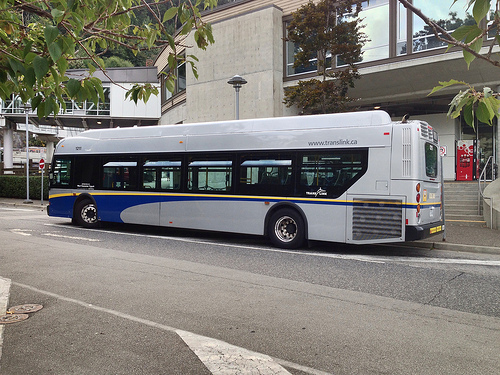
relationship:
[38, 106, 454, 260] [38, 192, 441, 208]
bus has a yellow stripe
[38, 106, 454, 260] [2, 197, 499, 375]
bus on a city street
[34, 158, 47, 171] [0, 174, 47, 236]
stop sign on corner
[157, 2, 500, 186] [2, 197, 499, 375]
building beside city street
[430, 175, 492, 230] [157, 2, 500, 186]
stairs are in front of building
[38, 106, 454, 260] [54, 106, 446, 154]
bus has a white roof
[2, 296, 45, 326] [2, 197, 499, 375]
man hole cover on city street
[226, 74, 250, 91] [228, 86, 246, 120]
street light on metal pole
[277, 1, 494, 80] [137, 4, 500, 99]
large window in upper floor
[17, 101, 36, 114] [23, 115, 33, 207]
street light on metal pole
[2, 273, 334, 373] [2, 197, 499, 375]
white lines painte on city street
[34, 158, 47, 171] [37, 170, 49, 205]
stop sign on a pole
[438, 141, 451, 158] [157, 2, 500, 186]
do not enter sign by building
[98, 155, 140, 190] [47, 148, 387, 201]
windows in a row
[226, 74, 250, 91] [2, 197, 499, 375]
street light next to city street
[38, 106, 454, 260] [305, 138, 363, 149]
bus company website www.translink.ca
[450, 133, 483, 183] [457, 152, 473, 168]
vending machine of soda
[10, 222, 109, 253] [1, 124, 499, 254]
white lines are for traffic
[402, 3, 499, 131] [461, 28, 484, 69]
tree has a leaf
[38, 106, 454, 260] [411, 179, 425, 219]
bus has signal lights